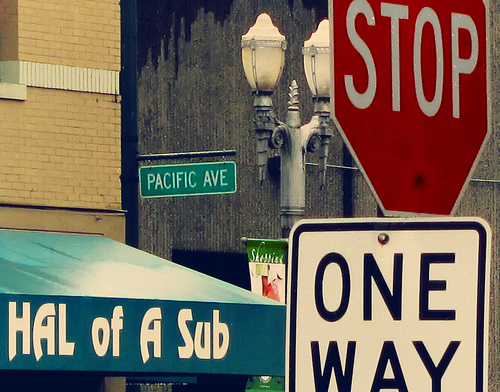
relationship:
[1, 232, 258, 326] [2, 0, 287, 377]
awning attached to building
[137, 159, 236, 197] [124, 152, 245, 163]
banner on pole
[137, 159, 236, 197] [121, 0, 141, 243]
banner on pole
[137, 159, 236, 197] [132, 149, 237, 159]
banner on pole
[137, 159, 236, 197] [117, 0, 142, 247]
banner on pole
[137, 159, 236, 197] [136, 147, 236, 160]
banner on pole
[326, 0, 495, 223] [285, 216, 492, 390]
stop sign above sign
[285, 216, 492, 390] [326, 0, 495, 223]
sign below stop sign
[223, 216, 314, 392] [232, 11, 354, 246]
green banner on pole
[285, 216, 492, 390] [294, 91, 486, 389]
sign on pole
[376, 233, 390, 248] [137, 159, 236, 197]
bolt on banner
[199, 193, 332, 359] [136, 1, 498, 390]
green banner hanging from building